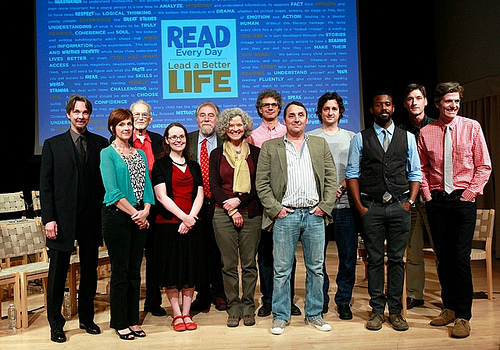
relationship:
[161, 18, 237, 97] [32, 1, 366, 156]
sign on screen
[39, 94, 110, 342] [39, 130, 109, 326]
man wearing suit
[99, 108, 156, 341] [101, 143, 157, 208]
woman wearing sweater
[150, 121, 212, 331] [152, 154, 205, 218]
woman wearing shirt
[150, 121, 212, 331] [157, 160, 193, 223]
woman wearing shirt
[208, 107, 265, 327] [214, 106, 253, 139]
woman has hair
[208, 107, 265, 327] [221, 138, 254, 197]
woman wearing scarf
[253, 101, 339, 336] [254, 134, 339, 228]
man wearing jacket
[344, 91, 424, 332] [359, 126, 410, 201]
man wearing vest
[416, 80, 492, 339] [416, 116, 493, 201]
man wearing shirt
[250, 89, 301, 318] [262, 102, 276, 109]
man wearing glasses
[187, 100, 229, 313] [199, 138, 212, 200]
man wearing tie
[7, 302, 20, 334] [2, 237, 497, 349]
water bottle on floor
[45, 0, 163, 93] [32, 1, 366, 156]
words on screen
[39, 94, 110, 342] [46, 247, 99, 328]
man wearing pants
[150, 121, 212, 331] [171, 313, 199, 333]
woman wearing shoes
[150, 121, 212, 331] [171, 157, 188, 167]
woman wearing necklace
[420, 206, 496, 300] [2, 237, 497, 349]
chair on floor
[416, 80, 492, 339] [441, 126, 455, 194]
man wearing tie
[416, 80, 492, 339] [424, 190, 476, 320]
man wearing pants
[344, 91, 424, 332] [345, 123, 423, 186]
man wearing shirt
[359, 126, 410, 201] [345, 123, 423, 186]
vest over shirt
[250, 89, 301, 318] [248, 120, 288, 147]
man wearing shirt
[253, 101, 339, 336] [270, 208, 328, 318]
man wearing jeans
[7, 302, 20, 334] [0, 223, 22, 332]
water bottle beneath chair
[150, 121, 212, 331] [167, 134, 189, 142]
woman wearing glasses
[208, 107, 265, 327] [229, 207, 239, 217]
woman wearing bracelet